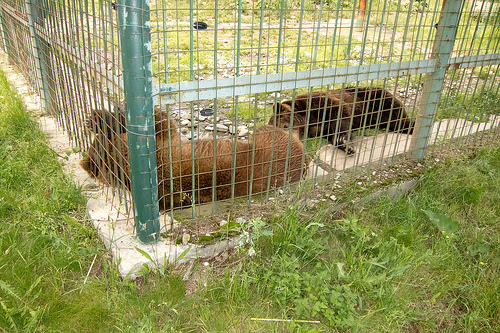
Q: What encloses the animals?
A: A wire fence.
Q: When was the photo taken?
A: Day time.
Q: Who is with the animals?
A: No one.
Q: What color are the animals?
A: Brown.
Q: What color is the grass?
A: Green.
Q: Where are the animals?
A: Inside a cage.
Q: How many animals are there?
A: 2.